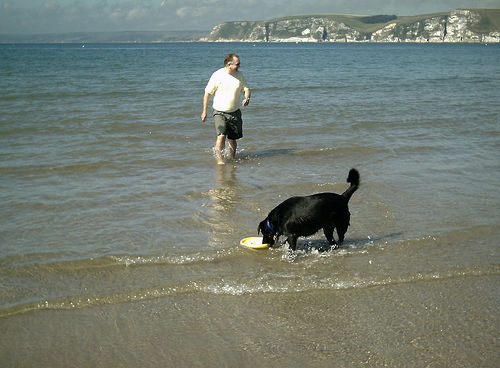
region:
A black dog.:
[253, 167, 358, 246]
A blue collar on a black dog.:
[261, 215, 273, 232]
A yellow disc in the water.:
[238, 237, 269, 249]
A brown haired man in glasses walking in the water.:
[201, 54, 251, 165]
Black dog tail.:
[343, 169, 360, 201]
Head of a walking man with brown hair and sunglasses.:
[222, 53, 243, 74]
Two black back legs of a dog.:
[322, 217, 348, 247]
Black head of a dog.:
[258, 219, 274, 248]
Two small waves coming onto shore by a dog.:
[2, 226, 499, 322]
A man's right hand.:
[201, 111, 207, 122]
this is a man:
[200, 48, 250, 143]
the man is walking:
[193, 47, 256, 155]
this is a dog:
[256, 165, 381, 253]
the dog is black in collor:
[288, 198, 334, 227]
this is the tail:
[342, 161, 367, 196]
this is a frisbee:
[240, 239, 275, 250]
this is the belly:
[214, 82, 241, 104]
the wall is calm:
[52, 45, 174, 152]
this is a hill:
[328, 11, 377, 34]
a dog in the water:
[245, 176, 377, 257]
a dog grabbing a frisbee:
[222, 187, 364, 258]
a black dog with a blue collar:
[250, 166, 377, 258]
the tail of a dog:
[337, 164, 367, 201]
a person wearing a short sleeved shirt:
[197, 48, 257, 112]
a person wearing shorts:
[210, 105, 248, 149]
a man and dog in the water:
[186, 35, 373, 275]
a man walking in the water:
[191, 42, 263, 167]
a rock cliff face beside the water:
[216, 20, 473, 51]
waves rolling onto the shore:
[81, 238, 206, 306]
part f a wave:
[159, 267, 215, 337]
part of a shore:
[241, 260, 272, 333]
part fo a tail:
[355, 185, 358, 204]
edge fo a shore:
[243, 258, 250, 283]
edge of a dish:
[252, 240, 261, 250]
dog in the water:
[236, 163, 376, 262]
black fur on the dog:
[256, 160, 376, 260]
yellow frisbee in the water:
[238, 228, 273, 254]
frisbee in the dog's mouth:
[226, 215, 277, 257]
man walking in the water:
[197, 52, 267, 176]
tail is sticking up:
[338, 159, 362, 198]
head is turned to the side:
[221, 53, 245, 73]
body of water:
[0, 40, 499, 329]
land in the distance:
[196, 8, 499, 44]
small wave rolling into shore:
[1, 260, 499, 330]